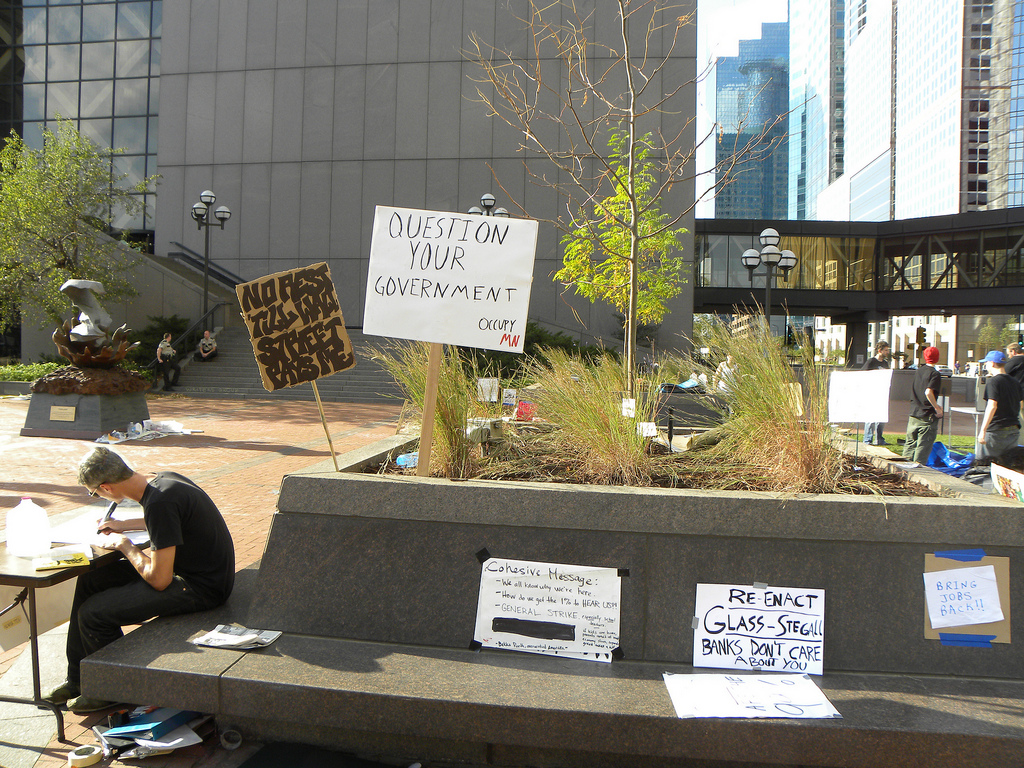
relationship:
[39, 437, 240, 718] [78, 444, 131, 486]
person has gray hair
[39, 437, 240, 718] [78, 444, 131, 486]
person has short hair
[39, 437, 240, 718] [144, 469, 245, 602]
person wears black shirt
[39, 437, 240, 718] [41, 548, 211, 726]
person wears pants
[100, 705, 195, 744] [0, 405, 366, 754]
blue notebook on ground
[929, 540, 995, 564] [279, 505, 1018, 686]
blue tape on wall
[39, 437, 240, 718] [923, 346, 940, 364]
person wears head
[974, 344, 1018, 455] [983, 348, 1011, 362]
person wears blue hat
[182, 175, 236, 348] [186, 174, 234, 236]
light pole has three lights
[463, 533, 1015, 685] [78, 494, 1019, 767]
three signs are on bench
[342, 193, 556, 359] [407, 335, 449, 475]
sign on stick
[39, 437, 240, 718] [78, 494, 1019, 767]
person sitting on bench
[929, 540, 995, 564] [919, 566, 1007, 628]
blue tape on paper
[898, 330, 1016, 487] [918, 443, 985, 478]
two people are on chairs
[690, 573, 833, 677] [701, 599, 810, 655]
white sign has black writing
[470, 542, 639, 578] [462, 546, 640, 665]
black tape holds white sign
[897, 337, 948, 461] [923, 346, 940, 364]
person wears head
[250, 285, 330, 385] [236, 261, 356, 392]
black writing on black writing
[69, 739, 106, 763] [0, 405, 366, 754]
duct tape on ground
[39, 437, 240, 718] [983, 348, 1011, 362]
person wears blue hat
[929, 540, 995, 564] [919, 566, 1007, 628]
blue tape holds up paper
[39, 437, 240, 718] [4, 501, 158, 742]
person leaning over table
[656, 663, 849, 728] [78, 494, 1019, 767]
sign laying on bench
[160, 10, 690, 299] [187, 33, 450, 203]
wall covered in windows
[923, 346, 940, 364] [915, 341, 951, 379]
head on head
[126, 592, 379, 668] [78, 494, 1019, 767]
shadow on bench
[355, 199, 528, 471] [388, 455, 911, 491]
posterboard in dirt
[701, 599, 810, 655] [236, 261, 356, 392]
black writing on black writing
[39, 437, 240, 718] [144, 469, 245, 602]
person wearing black shirt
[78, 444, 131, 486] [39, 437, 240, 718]
gray hair on person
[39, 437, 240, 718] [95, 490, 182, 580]
person has left arm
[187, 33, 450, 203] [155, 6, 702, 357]
windows are on building